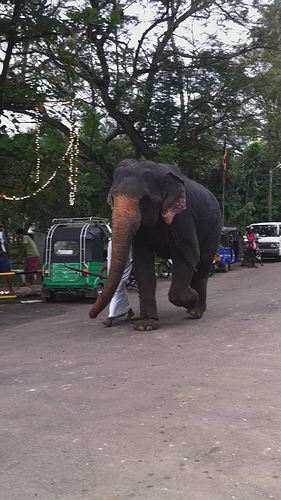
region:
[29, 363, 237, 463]
the pavement is gray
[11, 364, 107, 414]
spots are on pavement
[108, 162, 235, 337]
the elephant is walking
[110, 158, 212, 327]
the elephant is gray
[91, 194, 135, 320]
the elephant trunk is orange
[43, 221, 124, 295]
the cars are parked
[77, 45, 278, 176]
the trees are green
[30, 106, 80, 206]
the lights are hanging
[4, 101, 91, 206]
lights are in trees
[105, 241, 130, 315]
the clothes are white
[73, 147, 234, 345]
Elephant walking on road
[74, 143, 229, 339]
Elephant is dark brown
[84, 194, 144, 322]
Trunk of elephant is light brown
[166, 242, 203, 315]
Left leg of elephant is high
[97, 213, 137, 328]
Person walk next to elephant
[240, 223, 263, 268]
Person holds a kid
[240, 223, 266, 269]
Person wears red top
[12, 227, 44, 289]
Person wears green shirt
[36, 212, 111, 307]
Small car is green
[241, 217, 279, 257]
White van parked on left side of road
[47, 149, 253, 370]
An elephant walking down the street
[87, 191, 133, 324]
An elephant's trunk.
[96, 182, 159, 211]
The eyes of an elephant.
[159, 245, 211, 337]
Elephant's left front leg raised in the air.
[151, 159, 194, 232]
The left ear of an elephant.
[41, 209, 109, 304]
Green and black vehicle parked on street.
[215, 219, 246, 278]
Blue behicle parked on street.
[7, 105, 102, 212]
Strings of lights hanging in a tree.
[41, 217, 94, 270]
Silver railing on back of vehicle.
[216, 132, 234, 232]
A flag on haning a pole.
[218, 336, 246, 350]
white spot on the ground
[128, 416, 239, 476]
small brown smudges on the street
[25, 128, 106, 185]
cluster of lights in the trees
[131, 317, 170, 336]
elephant's broad foot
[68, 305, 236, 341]
shadow cast on the ground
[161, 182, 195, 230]
white spot on elephant's ear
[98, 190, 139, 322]
long black and brown elephant's trunk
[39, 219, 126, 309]
green and black mini car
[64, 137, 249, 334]
large elephant in the street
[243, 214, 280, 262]
white van parked on side of road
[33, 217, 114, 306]
a vehicle in the street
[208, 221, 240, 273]
a vehicle in the street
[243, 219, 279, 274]
a vehicle in the street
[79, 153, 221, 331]
a very big elephant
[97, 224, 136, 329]
a person in the street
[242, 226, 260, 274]
a person in the street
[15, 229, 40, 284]
a person in the street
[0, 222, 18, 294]
a person in the street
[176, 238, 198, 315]
the leg of an elephant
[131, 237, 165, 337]
the leg of an elephant